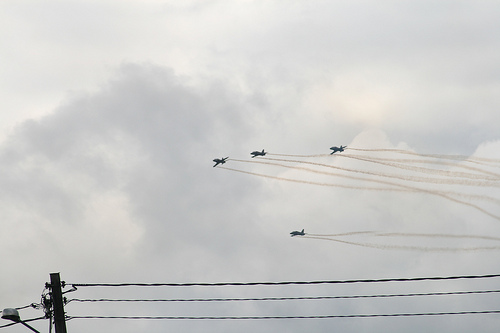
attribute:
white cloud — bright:
[302, 62, 414, 126]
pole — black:
[34, 274, 98, 331]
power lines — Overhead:
[85, 251, 489, 316]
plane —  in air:
[322, 138, 352, 159]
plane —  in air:
[239, 144, 275, 159]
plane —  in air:
[281, 221, 308, 237]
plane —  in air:
[203, 152, 227, 167]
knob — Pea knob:
[38, 279, 54, 294]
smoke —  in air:
[356, 134, 492, 279]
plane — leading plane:
[203, 145, 234, 174]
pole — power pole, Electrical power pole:
[45, 265, 67, 332]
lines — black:
[337, 260, 498, 321]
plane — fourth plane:
[307, 120, 387, 187]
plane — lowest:
[289, 229, 311, 239]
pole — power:
[49, 273, 69, 331]